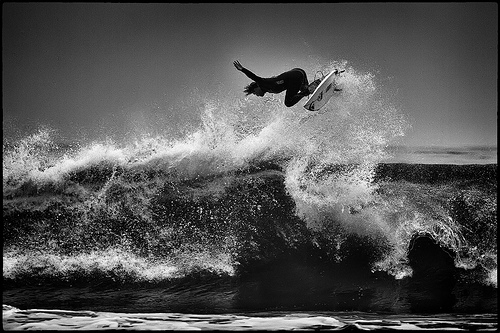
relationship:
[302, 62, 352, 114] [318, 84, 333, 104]
surfboard has black symbols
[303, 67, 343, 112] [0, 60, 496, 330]
surfboard in water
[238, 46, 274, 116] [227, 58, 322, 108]
head of man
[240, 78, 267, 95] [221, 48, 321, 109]
hair of man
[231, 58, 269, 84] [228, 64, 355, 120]
arm of man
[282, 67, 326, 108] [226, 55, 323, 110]
legs of man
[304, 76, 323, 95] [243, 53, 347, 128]
foot of man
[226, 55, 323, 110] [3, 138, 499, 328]
man riding wave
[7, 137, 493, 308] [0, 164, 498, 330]
wave in ocean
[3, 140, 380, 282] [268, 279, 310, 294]
wave in water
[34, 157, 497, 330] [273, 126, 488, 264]
seawater has high wave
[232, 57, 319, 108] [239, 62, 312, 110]
person wearing a wetsuit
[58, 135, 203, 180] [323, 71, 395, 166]
waves are making splash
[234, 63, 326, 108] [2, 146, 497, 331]
man in ocean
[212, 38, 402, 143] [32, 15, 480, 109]
surfer in air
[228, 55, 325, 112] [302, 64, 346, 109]
person on shortboard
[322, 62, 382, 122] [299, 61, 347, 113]
fins on surfboard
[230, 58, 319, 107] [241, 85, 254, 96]
surfer has hair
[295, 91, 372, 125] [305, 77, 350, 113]
logo on surfboard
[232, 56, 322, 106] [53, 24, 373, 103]
man in air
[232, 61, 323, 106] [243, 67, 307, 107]
man wearing wet suit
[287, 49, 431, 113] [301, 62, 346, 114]
surfboard has fins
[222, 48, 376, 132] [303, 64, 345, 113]
person on surfboard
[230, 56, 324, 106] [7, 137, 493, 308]
person surfing wave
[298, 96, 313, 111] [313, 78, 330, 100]
pony tip of surfboard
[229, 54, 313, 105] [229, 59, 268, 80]
person has arm